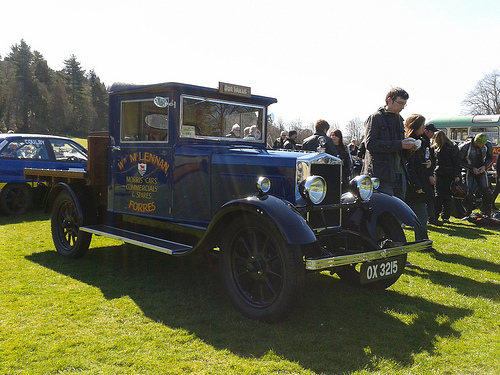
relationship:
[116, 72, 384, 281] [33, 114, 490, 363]
truck parked on grass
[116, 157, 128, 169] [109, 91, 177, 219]
word written on door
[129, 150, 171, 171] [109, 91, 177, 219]
word written on door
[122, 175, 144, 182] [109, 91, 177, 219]
word written on door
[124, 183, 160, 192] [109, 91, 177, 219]
word written on door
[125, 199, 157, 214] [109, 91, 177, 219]
word written on door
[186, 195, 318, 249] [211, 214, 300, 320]
fender over wheel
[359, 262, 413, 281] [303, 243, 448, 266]
license plate under bumper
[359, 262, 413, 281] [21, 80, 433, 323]
license plate of car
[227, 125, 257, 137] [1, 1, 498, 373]
people stand outside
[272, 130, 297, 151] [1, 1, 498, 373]
people stand outside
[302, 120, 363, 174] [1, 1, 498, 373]
people stand outside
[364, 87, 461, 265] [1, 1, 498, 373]
people stand outside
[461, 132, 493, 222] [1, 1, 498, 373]
people stand outside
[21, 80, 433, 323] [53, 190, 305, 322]
car has dark rims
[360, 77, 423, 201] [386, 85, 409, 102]
man with hair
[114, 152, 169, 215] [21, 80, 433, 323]
sign on car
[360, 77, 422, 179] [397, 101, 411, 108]
man wearing reading glasses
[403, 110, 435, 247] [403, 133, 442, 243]
woman wearing wearing jacket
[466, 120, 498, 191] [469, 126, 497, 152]
man wearing hat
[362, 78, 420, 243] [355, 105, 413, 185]
man walks with a jacket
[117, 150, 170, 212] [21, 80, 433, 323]
text on car